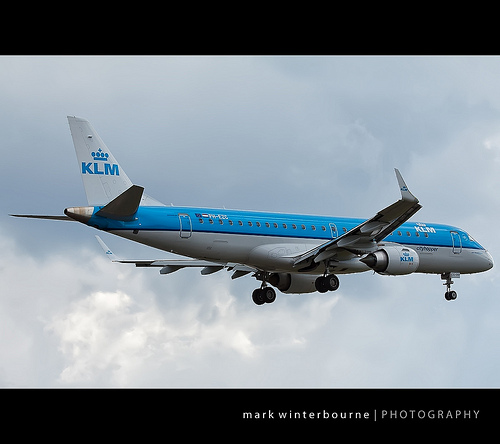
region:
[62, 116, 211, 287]
White tail on plane.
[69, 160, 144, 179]
KLM written in blue on the tail.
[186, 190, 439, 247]
Windows line the side of the plane.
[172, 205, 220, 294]
Door near tail of plane.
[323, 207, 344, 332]
Door near wing on plane.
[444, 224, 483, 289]
Door near front of plane.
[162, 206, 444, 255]
Top of plane is blue.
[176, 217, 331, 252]
Blue stripe in the middle section of plane.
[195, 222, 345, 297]
Bottom of plane is white in color.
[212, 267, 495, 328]
Landing gear on plane is down.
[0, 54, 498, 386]
an outdoor picture of a jet landing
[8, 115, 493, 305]
a KLM jet on approach for landing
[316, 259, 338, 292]
the jets landing gears are down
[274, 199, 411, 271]
the jets flap and aileron are adjusted down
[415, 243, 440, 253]
the jets name is the CityHopper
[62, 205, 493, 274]
the jets fuselage is painted blue and gray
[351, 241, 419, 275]
the jets engine is mounted on the wing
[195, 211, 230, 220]
the jets identification number is displayed on the fuselage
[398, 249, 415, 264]
the KLM logo is displayed on the engine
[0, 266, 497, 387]
the sky is cloudy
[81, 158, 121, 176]
Blue letters KLM on the tail of a plane.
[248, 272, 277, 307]
Back landing gear and wheels.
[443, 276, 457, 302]
Very front set of landing gear on a plane.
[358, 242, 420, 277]
Right side engine with KLM written on it.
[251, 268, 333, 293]
Left side engine of an airplane.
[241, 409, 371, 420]
mark winterbourne watermark on the photo.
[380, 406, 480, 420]
The word PHOTOGRAPHY.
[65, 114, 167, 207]
The back tail end wing of the plane.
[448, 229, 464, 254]
Front side door of a blue, gray and white plane.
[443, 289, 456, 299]
Two front wheels of an airplane.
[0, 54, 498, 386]
an outdoor scene of a jet landing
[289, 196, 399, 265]
the jet flaps are in a down position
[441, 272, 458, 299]
the landing gears are in a down position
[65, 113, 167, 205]
the jets tail has the name and logo of the airline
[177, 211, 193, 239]
the rear cabin door is to the rear of the passenger windows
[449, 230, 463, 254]
the front cabin door is also the cockpit door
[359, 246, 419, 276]
the jet engine is mounted to the wing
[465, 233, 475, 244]
the cockpit windshield is at the front of the jet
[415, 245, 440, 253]
the jets ID name is the Cityhopper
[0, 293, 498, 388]
the sky is cloudy with the sun peaking through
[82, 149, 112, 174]
writing on tail of airplane.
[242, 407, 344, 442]
logo on bottom of picture.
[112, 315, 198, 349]
clouds in the sky.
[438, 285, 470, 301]
wheel at front of plane.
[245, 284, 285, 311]
wheel in middle of plane.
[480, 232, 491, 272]
nose of the airplane.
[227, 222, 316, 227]
windows along the airplane.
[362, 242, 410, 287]
engine of the airplane.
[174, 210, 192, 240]
back door of airplane.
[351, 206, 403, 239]
wing of the airplane.